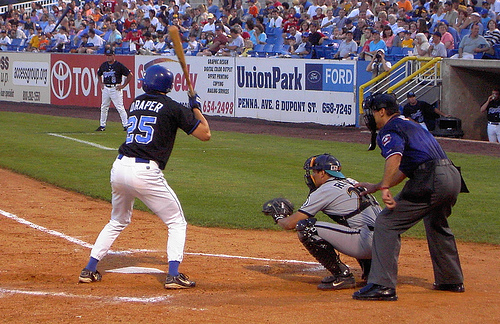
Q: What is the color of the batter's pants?
A: White.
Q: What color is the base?
A: White.